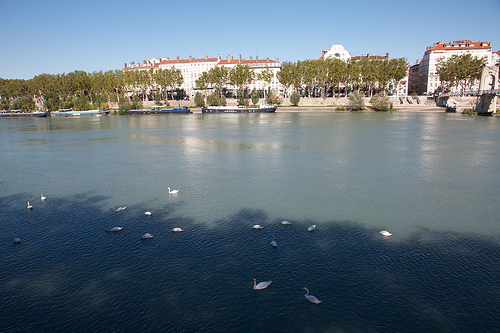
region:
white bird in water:
[376, 229, 393, 237]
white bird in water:
[301, 283, 321, 308]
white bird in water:
[250, 274, 272, 294]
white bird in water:
[271, 237, 281, 248]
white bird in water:
[303, 223, 318, 230]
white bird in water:
[276, 217, 293, 229]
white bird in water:
[251, 220, 266, 232]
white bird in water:
[167, 224, 183, 234]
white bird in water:
[163, 178, 184, 200]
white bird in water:
[103, 220, 123, 237]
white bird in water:
[40, 194, 48, 203]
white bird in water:
[24, 198, 36, 211]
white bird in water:
[6, 228, 23, 242]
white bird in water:
[108, 200, 128, 217]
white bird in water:
[140, 207, 157, 218]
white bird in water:
[141, 230, 153, 242]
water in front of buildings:
[8, 128, 496, 315]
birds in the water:
[11, 188, 408, 318]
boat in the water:
[198, 100, 278, 117]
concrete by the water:
[288, 98, 477, 109]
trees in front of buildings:
[8, 67, 480, 100]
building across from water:
[128, 45, 289, 95]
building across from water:
[416, 41, 496, 87]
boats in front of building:
[51, 106, 196, 127]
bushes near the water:
[346, 90, 396, 109]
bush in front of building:
[286, 95, 303, 110]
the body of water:
[0, 108, 499, 331]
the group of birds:
[12, 186, 392, 302]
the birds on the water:
[11, 187, 393, 304]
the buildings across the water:
[120, 39, 498, 98]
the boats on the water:
[0, 105, 277, 115]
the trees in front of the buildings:
[0, 53, 487, 108]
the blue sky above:
[0, 0, 498, 81]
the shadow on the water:
[0, 189, 499, 331]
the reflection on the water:
[0, 110, 499, 166]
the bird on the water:
[252, 276, 274, 290]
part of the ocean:
[166, 279, 171, 302]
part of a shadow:
[241, 277, 251, 294]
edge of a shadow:
[358, 233, 368, 249]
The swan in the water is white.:
[241, 268, 270, 295]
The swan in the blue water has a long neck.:
[300, 281, 325, 308]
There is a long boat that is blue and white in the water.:
[193, 99, 280, 118]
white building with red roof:
[139, 54, 284, 96]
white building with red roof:
[423, 34, 488, 95]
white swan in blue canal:
[239, 269, 278, 296]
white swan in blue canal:
[299, 276, 328, 311]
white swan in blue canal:
[374, 217, 397, 245]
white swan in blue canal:
[246, 216, 267, 231]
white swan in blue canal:
[166, 178, 186, 200]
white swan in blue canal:
[111, 217, 134, 232]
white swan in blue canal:
[137, 223, 163, 242]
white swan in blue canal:
[169, 217, 190, 240]